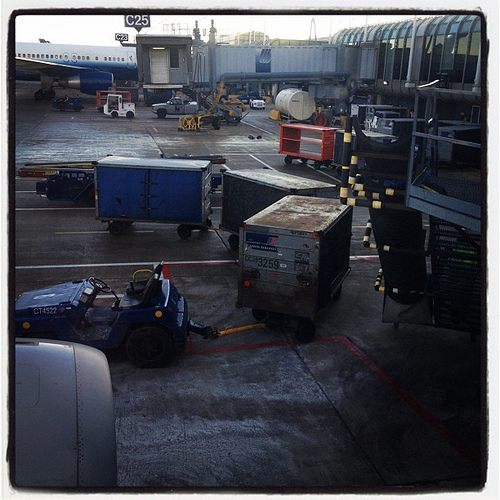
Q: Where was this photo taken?
A: An airport.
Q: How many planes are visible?
A: One.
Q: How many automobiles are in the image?
A: Five.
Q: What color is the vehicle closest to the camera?
A: Blue.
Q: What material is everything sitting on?
A: Cement.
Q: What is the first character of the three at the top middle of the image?
A: C.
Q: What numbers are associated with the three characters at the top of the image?
A: 25.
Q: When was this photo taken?
A: Day time.